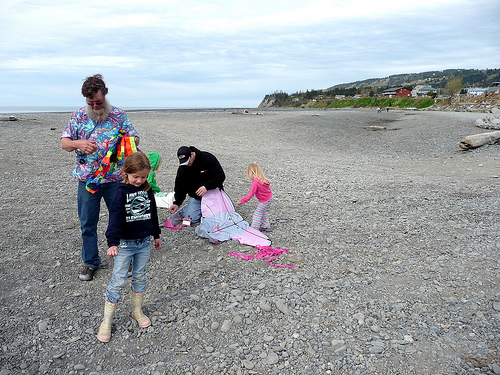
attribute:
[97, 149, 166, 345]
girl — little, looking, young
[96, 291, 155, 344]
boots — pastel, multi-colored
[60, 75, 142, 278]
man — large, looking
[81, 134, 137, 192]
kite — pink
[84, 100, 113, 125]
beard — grey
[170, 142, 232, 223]
man — looking, kneeling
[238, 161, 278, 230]
girl — looking, young, little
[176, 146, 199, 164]
hat — black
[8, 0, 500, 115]
sky — blue, vast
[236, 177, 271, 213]
shirt — pink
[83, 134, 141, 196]
towel — rainbow colored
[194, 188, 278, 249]
kite — dumbo kite, large, shaped, grey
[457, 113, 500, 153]
piece — worn, driftwood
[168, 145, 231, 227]
person — kneeling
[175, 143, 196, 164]
cap — black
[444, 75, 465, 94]
tree — light green, large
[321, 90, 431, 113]
patch — grass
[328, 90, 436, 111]
grass — green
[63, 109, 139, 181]
shirt — tie-dyed, colorful, man's, pink, blue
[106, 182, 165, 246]
sweatshirt — navy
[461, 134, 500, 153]
log — large, driftwood, here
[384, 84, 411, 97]
building — red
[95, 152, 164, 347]
child — wearing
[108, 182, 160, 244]
shirt — black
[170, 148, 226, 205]
shirt — black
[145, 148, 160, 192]
sweater — green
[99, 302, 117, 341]
boot — child's, rubber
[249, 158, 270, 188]
hair — blond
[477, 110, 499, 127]
driftwood — large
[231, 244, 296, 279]
tassels — hot pink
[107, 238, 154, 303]
jeans — girl's, blue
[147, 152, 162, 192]
sweatshirt — small, green, hooded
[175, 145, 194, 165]
basball hat — black, white